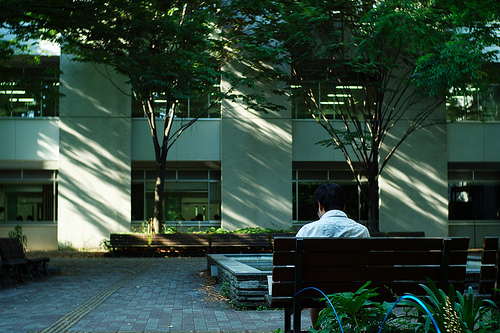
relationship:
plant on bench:
[297, 282, 384, 332] [106, 234, 150, 255]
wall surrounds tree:
[12, 16, 494, 241] [252, 4, 489, 238]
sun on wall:
[17, 49, 449, 238] [12, 16, 494, 241]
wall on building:
[12, 16, 494, 241] [1, 0, 499, 250]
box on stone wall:
[207, 266, 218, 278] [204, 257, 246, 312]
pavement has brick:
[1, 257, 296, 331] [215, 308, 225, 317]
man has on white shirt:
[293, 183, 370, 238] [292, 207, 371, 235]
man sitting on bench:
[293, 183, 370, 238] [265, 225, 472, 330]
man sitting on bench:
[293, 180, 375, 238] [261, 233, 476, 328]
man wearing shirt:
[293, 183, 370, 238] [297, 206, 367, 235]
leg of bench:
[291, 310, 306, 328] [263, 233, 498, 330]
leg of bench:
[283, 307, 293, 328] [263, 233, 498, 330]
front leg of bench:
[284, 306, 293, 329] [263, 233, 498, 330]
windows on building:
[3, 171, 56, 222] [1, 0, 499, 250]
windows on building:
[295, 167, 373, 217] [1, 0, 499, 250]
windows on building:
[451, 167, 499, 217] [1, 0, 499, 250]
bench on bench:
[208, 222, 270, 248] [265, 225, 472, 330]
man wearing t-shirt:
[293, 183, 370, 238] [287, 210, 377, 240]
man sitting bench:
[293, 183, 370, 238] [188, 176, 483, 317]